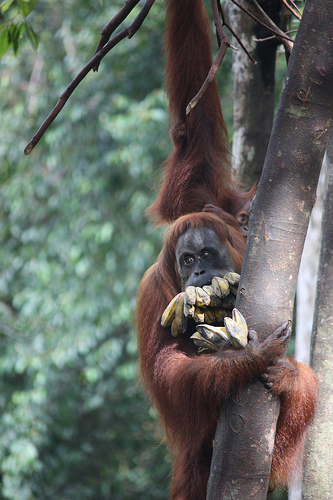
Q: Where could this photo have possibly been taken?
A: Zoo.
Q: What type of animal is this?
A: Monkey.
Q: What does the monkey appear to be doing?
A: Climbing.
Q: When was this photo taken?
A: Daytime.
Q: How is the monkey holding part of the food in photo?
A: In mouth.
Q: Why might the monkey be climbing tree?
A: To hide food.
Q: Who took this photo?
A: Photographer.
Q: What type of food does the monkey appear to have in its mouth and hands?
A: Bananas.